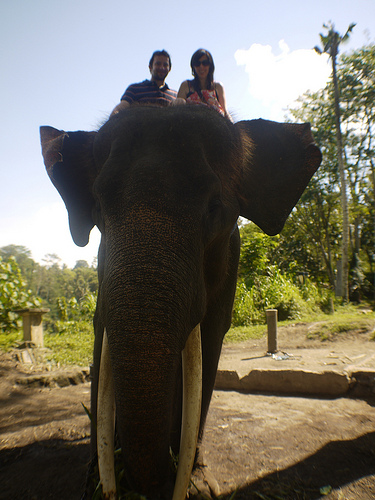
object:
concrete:
[1, 368, 375, 498]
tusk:
[172, 321, 203, 499]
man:
[109, 48, 185, 119]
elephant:
[37, 94, 323, 496]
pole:
[263, 306, 279, 354]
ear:
[38, 122, 104, 249]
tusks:
[95, 324, 125, 497]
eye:
[209, 194, 228, 213]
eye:
[93, 189, 119, 216]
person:
[175, 47, 230, 124]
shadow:
[3, 430, 375, 498]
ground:
[0, 312, 375, 498]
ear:
[234, 115, 327, 239]